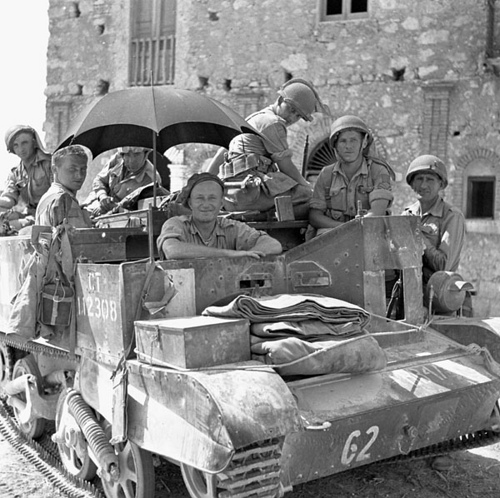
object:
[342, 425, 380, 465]
lettering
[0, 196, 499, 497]
tank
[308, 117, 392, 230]
soldier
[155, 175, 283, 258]
soldier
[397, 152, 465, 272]
soldier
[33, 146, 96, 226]
soldier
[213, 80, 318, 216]
soldier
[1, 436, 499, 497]
ground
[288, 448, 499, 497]
dirt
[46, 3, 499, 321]
stone wall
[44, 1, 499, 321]
building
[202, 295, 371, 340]
blankets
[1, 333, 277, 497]
tank treads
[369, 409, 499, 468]
tank treads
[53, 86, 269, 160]
unbrella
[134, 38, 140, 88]
wood bars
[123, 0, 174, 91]
window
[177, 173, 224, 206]
hat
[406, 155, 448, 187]
helmet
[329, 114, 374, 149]
helmet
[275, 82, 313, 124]
helmet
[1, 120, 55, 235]
soldier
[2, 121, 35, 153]
helmet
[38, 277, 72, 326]
canteen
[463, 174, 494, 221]
window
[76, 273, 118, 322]
lettering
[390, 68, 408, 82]
hole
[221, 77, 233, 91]
hole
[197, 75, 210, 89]
hole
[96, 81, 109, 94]
hole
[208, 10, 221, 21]
hole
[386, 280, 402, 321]
gun barrel